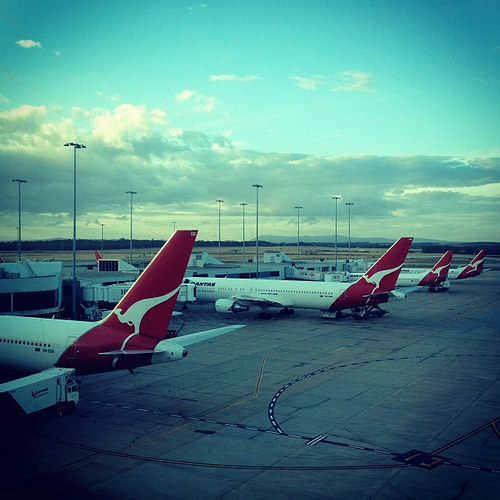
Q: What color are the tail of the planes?
A: Red.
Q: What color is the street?
A: Black.